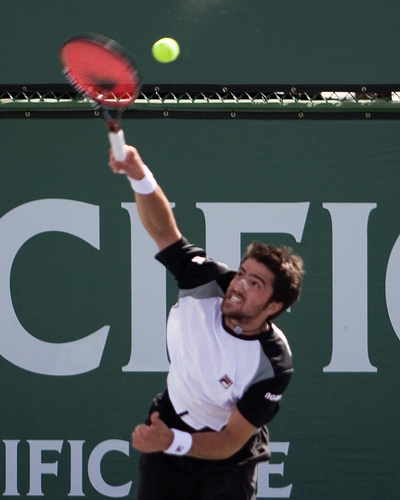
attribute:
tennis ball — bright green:
[147, 35, 180, 68]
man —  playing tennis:
[96, 139, 312, 498]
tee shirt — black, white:
[152, 231, 301, 436]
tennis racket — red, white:
[51, 26, 145, 164]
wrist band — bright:
[163, 425, 195, 458]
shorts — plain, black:
[126, 395, 262, 498]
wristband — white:
[127, 165, 159, 195]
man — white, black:
[108, 142, 304, 494]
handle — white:
[96, 105, 127, 174]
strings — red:
[67, 41, 138, 107]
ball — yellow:
[152, 36, 178, 62]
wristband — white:
[164, 428, 192, 456]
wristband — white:
[129, 168, 156, 199]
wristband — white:
[160, 424, 193, 456]